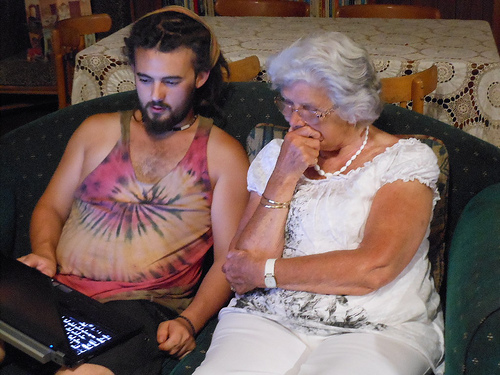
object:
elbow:
[352, 249, 393, 294]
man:
[33, 22, 250, 334]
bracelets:
[261, 194, 290, 210]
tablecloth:
[69, 13, 496, 149]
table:
[67, 16, 496, 138]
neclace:
[310, 124, 372, 179]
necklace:
[171, 112, 198, 130]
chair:
[40, 11, 121, 102]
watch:
[264, 258, 279, 291]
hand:
[274, 123, 321, 181]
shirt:
[51, 109, 210, 300]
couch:
[5, 82, 497, 374]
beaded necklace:
[303, 126, 370, 177]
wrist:
[259, 167, 297, 200]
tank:
[48, 107, 220, 300]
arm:
[232, 130, 321, 277]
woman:
[204, 35, 463, 369]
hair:
[125, 14, 226, 118]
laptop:
[0, 250, 146, 371]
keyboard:
[44, 312, 115, 356]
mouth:
[290, 129, 322, 143]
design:
[400, 59, 475, 103]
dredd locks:
[125, 8, 224, 124]